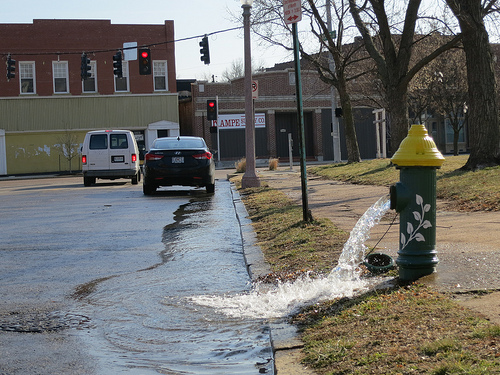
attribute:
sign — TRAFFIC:
[283, 4, 302, 23]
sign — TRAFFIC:
[252, 80, 261, 99]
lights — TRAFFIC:
[200, 36, 210, 66]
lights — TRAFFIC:
[136, 45, 152, 73]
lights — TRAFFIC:
[109, 48, 126, 79]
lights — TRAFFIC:
[80, 60, 92, 82]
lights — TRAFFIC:
[2, 56, 22, 82]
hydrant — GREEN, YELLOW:
[383, 108, 443, 281]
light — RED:
[132, 46, 156, 78]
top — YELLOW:
[387, 124, 447, 167]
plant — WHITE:
[395, 190, 432, 256]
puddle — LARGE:
[107, 212, 272, 353]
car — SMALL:
[136, 132, 214, 192]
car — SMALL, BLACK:
[139, 131, 217, 197]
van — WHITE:
[75, 117, 140, 188]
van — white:
[81, 127, 141, 185]